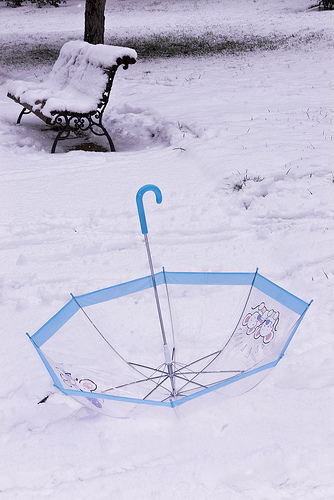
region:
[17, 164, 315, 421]
upside down blue umbrella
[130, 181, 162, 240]
blue plastic umbrella handle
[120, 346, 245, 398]
metal framework of umbrella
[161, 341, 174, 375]
white plastic umbrella mechanism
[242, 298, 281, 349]
upside down design on umbrella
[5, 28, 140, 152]
metal bench covered in snow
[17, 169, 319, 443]
umbrella left in the snow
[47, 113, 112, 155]
black metal scrollwork on bottom of bench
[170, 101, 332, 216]
bits of dark grass poking through snow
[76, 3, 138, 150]
wide dark tree trunk behind bench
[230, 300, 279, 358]
Two upside down cartoon mice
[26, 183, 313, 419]
Large transparent upside down umbrella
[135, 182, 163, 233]
Blue cane shaped handle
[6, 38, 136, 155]
Iron bench covered in snow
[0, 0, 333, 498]
Ground covered in snow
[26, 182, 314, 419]
Umbrella resting in the snow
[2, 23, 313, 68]
Patch of grass without snow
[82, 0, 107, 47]
Brown bark tree trunk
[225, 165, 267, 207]
Grass peaking out of the snow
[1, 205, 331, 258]
Footprints in the snow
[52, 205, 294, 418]
Umbrella on the ground.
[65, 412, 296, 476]
Snow on the ground.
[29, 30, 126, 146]
Bench in the snow.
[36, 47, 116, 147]
Snow on the bench.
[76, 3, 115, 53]
Tree trunk of a tree.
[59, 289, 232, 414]
The umbrella is plastic.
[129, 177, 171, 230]
The umbrella handle is blue.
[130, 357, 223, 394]
Wires on the umbrella.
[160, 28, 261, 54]
Grass around the tree.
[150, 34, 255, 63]
Snow on the grass.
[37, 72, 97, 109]
snow on the bench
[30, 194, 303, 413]
an upside down umbrella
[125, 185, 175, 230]
handle of the umbrella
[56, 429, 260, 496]
the snow is white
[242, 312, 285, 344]
design on the umbrella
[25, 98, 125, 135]
the bench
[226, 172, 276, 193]
grass is covered in snow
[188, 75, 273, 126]
the snow on the ground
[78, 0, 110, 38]
a tree trunk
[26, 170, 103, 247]
the snow is white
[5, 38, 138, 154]
a bench covered with snow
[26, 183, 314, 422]
a blue umbrella on the ground covered with snow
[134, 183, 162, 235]
a blue handle of the umbrella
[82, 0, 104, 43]
a bark of a tree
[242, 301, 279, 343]
a print on the umbrella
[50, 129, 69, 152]
a leg of the bench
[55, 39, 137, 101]
a backrest of the bench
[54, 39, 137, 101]
a backrest of the bench covered with snow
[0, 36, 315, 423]
an umbrella next to the bench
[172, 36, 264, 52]
grass partially covered with snow